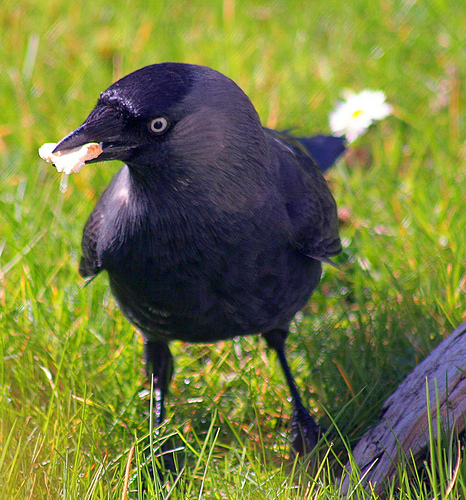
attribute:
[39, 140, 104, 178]
bread — white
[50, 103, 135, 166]
beak — black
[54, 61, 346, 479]
bird — black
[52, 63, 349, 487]
raven — black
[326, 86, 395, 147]
flower — white, yellow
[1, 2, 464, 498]
grass — green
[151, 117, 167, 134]
eye — gray, silver, black, white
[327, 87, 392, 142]
daisy — yellow, white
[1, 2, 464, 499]
field — grassy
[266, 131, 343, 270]
wing — black